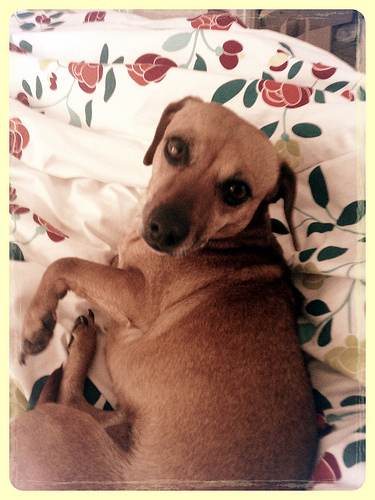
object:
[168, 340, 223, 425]
fur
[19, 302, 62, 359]
paw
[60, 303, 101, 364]
paw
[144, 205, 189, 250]
nose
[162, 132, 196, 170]
eye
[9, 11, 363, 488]
bed cover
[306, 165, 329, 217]
leaves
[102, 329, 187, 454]
stomach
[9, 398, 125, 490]
hip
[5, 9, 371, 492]
sheet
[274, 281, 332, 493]
back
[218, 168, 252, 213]
ring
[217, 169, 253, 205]
eye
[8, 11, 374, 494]
blanket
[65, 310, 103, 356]
claws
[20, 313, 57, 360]
pads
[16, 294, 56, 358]
feet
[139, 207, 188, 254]
nose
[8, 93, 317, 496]
dog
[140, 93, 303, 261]
head